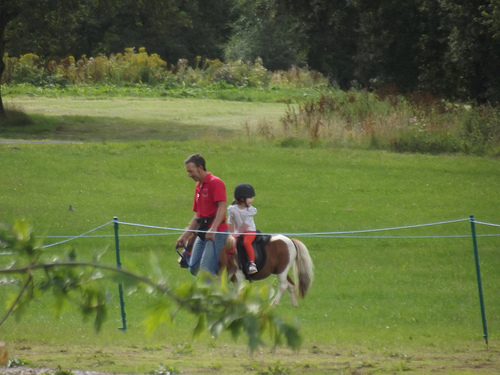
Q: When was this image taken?
A: During the day.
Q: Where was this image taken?
A: On a field.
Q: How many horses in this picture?
A: One.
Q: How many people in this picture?
A: Two.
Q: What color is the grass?
A: Green.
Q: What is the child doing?
A: Riding a horse.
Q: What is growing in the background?
A: Trees.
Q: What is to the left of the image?
A: A branch.